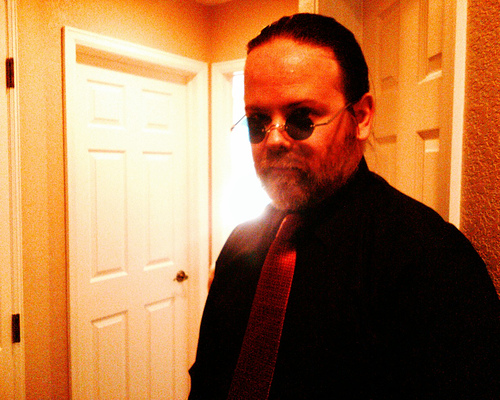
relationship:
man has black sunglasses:
[182, 11, 498, 398] [232, 110, 349, 136]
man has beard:
[182, 11, 498, 398] [249, 119, 364, 216]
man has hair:
[182, 11, 498, 398] [249, 5, 371, 95]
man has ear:
[182, 11, 498, 398] [354, 90, 375, 140]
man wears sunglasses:
[182, 11, 498, 398] [232, 110, 345, 143]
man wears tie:
[182, 11, 498, 398] [228, 216, 303, 396]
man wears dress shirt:
[182, 11, 498, 398] [178, 161, 500, 399]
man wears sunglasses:
[182, 11, 498, 398] [231, 112, 358, 142]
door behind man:
[351, 1, 456, 237] [215, 31, 406, 372]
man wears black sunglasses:
[182, 11, 498, 398] [239, 117, 312, 145]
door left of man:
[61, 30, 209, 398] [182, 11, 498, 398]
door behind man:
[351, 1, 456, 237] [182, 11, 498, 398]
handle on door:
[172, 269, 188, 282] [77, 51, 194, 397]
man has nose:
[182, 11, 498, 398] [264, 113, 294, 153]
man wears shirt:
[182, 11, 498, 398] [187, 154, 499, 399]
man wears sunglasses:
[182, 11, 498, 398] [224, 99, 363, 142]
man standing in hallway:
[182, 11, 498, 398] [1, 0, 498, 398]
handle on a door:
[176, 270, 186, 282] [61, 30, 209, 398]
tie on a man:
[228, 216, 303, 396] [182, 11, 498, 398]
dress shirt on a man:
[185, 183, 473, 356] [182, 11, 498, 398]